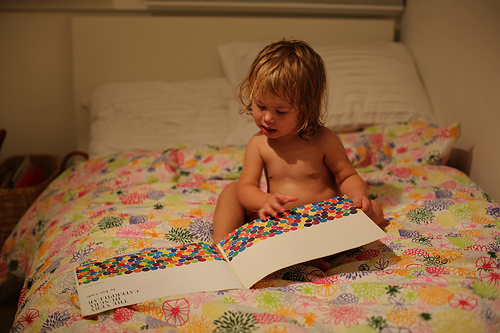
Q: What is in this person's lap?
A: Book.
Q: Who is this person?
A: Toddler.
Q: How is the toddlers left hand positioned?
A: Holding book.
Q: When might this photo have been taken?
A: Bedtime.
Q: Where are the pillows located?
A: Behind toddler.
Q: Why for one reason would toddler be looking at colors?
A: Fascinated.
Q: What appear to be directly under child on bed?
A: Comforter.